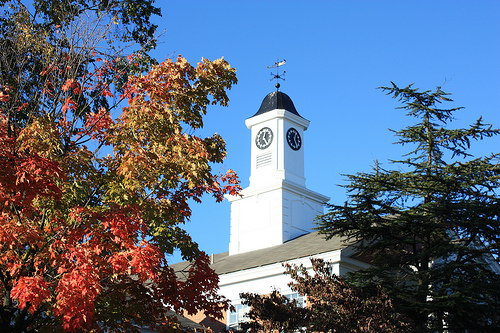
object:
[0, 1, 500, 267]
sky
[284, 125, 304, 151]
clock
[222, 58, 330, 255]
tower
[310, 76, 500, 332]
tree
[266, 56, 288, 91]
weather vane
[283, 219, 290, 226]
tiles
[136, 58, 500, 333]
building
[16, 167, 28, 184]
light leaves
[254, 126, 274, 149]
clock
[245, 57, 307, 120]
spire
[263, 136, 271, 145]
clock hand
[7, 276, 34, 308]
leaves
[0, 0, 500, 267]
cloud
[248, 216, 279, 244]
white